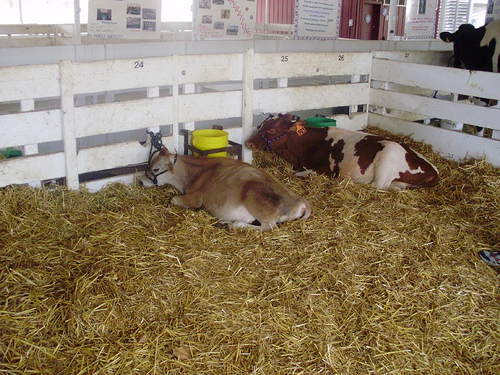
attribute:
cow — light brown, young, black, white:
[139, 142, 313, 232]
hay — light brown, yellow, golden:
[1, 125, 499, 374]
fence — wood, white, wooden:
[1, 26, 500, 194]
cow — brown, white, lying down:
[245, 112, 440, 192]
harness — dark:
[145, 130, 179, 187]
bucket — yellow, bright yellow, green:
[191, 128, 228, 158]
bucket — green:
[305, 116, 336, 129]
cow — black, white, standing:
[440, 20, 500, 137]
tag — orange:
[295, 123, 307, 137]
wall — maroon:
[256, 0, 442, 40]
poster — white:
[88, 0, 161, 42]